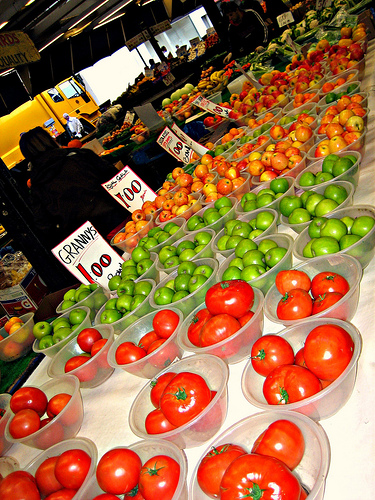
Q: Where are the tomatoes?
A: On the table.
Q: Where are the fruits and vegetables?
A: On the table.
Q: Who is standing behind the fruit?
A: A person.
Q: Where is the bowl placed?
A: In the table.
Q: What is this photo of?
A: A market.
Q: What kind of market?
A: A farmer's.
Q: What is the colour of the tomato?
A: Red.